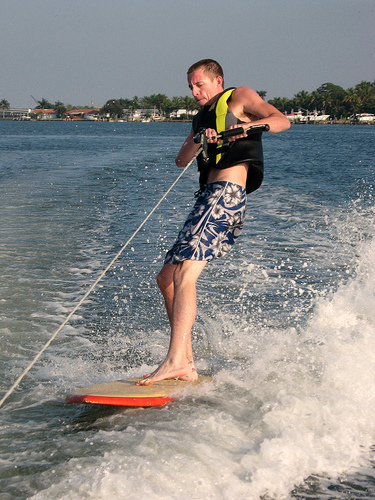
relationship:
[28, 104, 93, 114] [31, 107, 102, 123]
roofs on buildings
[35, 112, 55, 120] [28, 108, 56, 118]
wall on side of building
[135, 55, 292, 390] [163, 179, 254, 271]
man wearing shorts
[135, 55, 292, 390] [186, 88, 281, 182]
man wearing vest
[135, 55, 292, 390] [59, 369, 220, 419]
man standing on surfboard